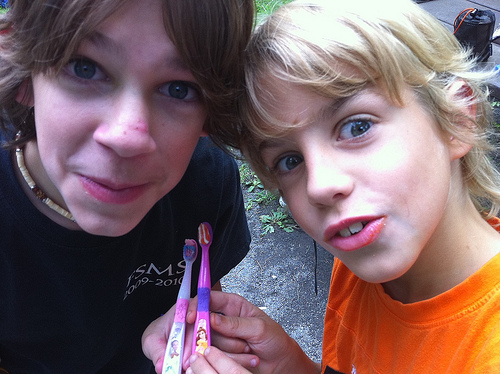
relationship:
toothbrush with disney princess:
[193, 215, 220, 360] [190, 323, 214, 359]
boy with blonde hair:
[197, 7, 499, 369] [230, 2, 499, 219]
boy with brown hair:
[1, 3, 262, 371] [4, 0, 260, 173]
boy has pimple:
[1, 3, 262, 371] [128, 116, 150, 139]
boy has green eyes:
[197, 7, 499, 369] [260, 105, 383, 182]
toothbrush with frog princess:
[159, 232, 197, 373] [161, 334, 185, 371]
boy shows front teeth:
[197, 7, 499, 369] [336, 217, 371, 241]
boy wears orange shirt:
[197, 7, 499, 369] [313, 251, 498, 373]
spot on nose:
[128, 116, 150, 139] [87, 84, 162, 163]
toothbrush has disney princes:
[159, 232, 197, 373] [161, 334, 185, 371]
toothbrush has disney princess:
[193, 215, 220, 360] [190, 323, 214, 359]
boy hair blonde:
[197, 7, 499, 369] [230, 2, 499, 219]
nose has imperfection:
[87, 84, 162, 163] [128, 116, 150, 139]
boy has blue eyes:
[1, 3, 262, 371] [56, 46, 210, 111]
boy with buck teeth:
[197, 7, 499, 369] [336, 217, 371, 241]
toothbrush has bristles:
[193, 215, 220, 360] [194, 217, 215, 251]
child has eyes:
[197, 7, 499, 369] [260, 105, 383, 182]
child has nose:
[197, 7, 499, 369] [294, 137, 359, 213]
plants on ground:
[233, 159, 301, 250] [233, 169, 329, 355]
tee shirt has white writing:
[0, 136, 250, 374] [116, 252, 196, 307]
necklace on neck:
[6, 127, 78, 225] [13, 138, 80, 243]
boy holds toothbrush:
[197, 7, 499, 369] [193, 215, 220, 360]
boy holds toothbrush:
[1, 3, 262, 371] [159, 232, 197, 373]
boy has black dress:
[1, 3, 262, 371] [0, 136, 250, 374]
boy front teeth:
[197, 7, 499, 369] [336, 217, 371, 241]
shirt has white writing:
[0, 136, 250, 374] [116, 252, 196, 307]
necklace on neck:
[6, 127, 78, 225] [13, 129, 90, 236]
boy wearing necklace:
[1, 3, 262, 371] [6, 127, 78, 225]